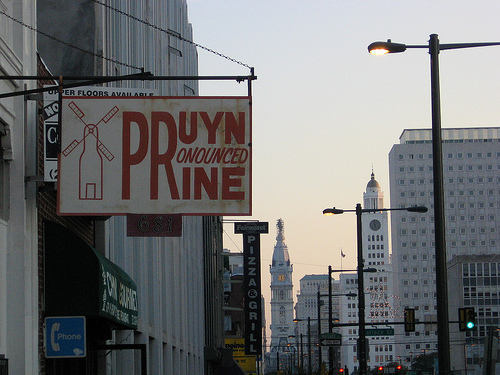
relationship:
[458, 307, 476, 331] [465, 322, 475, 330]
signal on light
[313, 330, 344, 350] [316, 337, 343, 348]
sign on arrow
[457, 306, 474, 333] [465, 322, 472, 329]
signal has light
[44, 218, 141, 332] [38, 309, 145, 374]
canopy over doorway